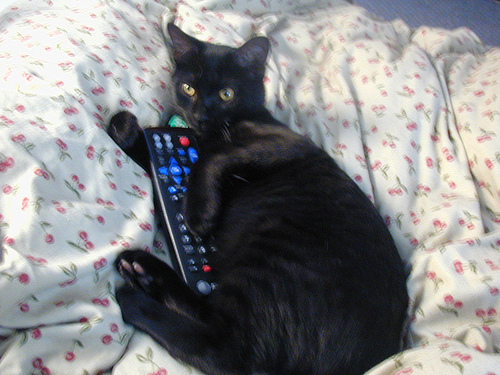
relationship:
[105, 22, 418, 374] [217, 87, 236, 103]
cat has eye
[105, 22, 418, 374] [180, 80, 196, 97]
cat has eye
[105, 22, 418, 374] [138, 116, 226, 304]
cat holding remote control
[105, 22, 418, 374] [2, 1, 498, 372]
cat laying on a blanket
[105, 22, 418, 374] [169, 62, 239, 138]
cat has face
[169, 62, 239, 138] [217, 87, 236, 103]
face has eye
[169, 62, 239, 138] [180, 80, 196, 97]
face has eye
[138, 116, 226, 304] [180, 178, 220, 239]
remote control under paw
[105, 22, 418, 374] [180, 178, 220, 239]
cat has paw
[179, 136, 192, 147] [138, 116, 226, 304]
button on remote control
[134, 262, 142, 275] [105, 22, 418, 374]
paw pad on cat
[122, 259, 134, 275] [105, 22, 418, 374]
paw pad on cat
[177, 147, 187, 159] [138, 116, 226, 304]
button on remote control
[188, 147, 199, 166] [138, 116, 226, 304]
button on remote control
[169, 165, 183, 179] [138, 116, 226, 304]
button on remote control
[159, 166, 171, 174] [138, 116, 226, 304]
button on remote control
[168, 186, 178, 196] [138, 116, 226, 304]
button on remote control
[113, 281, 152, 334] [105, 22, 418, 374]
back paw on cat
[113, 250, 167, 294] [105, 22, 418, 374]
back paw on cat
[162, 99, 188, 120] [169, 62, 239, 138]
whiskers on face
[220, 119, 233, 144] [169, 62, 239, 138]
left whiskers on face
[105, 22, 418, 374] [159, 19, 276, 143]
cat has head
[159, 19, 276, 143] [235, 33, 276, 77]
head has ear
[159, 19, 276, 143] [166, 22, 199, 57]
head has ear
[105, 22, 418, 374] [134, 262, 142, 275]
cat has paw pad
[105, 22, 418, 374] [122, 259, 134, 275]
cat has paw pad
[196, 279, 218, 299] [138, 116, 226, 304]
button on remote control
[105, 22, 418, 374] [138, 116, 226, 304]
cat has a remote control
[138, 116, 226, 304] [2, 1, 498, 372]
remote control on a blanket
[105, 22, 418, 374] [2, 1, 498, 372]
cat on a blanket